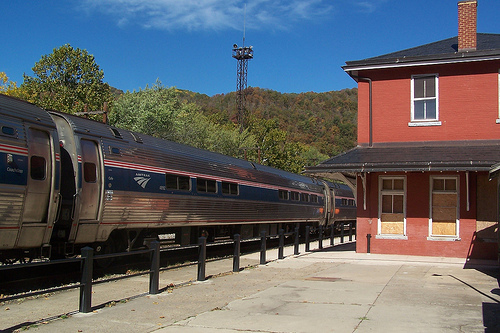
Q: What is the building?
A: Train station.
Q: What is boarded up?
A: Some of the windows.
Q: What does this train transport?
A: Human beings.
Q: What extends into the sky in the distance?
A: A tower.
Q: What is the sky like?
A: Almost completely clear.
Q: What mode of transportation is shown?
A: Train.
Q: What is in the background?
A: Trees.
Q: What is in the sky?
A: Clouds.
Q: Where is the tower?
A: In and above the trees.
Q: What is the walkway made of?
A: Concrete.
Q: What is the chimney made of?
A: Brick.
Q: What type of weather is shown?
A: Sunny.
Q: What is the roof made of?
A: Shingles.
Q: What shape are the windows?
A: Rectangle.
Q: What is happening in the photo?
A: An amtrak train has arrived at the station.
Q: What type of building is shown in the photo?
A: A train station.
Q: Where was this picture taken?
A: At a train station.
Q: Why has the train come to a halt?
A: It has reached a station.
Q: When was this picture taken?
A: During daylight.